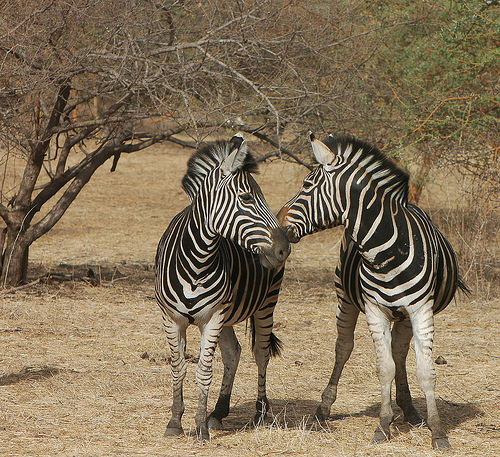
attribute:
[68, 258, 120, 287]
objects — dark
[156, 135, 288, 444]
zebra — playing, white, standing, nosing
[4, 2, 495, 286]
tree — green, wide, bent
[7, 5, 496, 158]
leaves — green, hanging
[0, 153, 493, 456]
ground — dry, brown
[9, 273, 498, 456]
dirt — brown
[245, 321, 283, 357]
tail — black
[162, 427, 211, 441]
knuckle — fat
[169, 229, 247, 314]
stripe — black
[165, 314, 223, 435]
leg — white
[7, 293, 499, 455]
grass — dry, burnt, brown